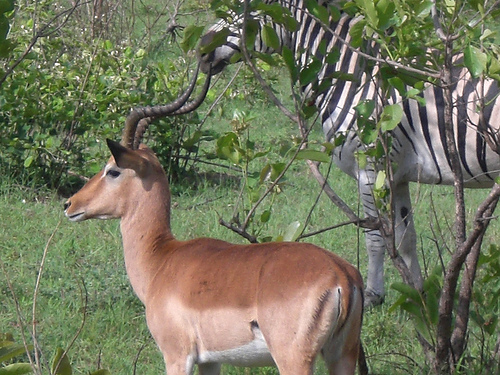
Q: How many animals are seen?
A: Two.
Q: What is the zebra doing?
A: Looking.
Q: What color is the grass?
A: Green.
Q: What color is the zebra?
A: Black and white.